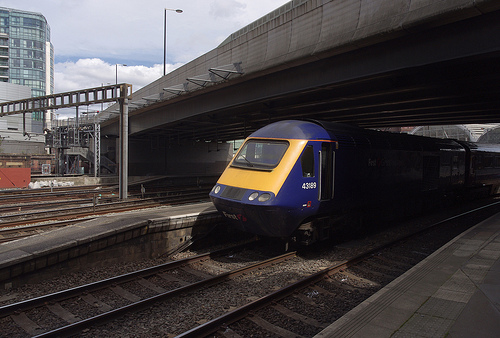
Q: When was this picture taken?
A: During the day.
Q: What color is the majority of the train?
A: Blue.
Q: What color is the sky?
A: Blue.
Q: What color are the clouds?
A: White.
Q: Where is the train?
A: On the tracks.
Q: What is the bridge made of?
A: Concrete.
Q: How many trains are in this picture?
A: One.